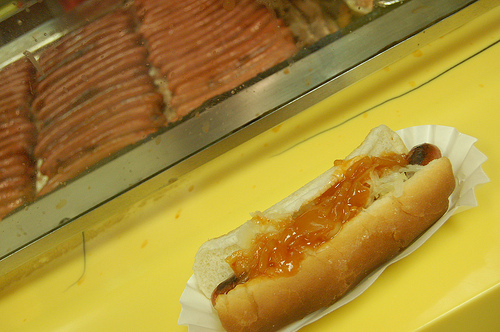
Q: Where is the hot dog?
A: In a wrapper.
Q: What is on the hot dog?
A: Sauce and onions.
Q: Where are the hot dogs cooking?
A: On the rack.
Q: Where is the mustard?
A: On top of the hot dog.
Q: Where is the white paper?
A: Under the hot dog.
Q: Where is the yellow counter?
A: By the hot dog.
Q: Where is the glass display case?
A: Behind the hot dog.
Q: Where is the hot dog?
A: In a paper holder.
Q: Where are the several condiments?
A: On the hot dog.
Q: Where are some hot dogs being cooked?
A: In the glass case.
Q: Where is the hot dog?
A: In a bun.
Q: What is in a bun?
A: The hot dog.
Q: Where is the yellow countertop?
A: Under the hot dog.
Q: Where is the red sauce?
A: On the hot dog.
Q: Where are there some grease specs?
A: On the glass.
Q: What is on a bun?
A: Hot dog.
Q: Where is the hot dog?
A: On a counter.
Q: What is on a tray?
A: Bun.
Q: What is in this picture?
A: White tray with a hot dog on top.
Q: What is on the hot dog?
A: Sauce.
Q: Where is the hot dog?
A: On a yellow counter.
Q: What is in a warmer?
A: Hot dogs.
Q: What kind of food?
A: Grilled hot dog with grilled onions.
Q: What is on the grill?
A: Hot dogs.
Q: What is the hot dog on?
A: Paper.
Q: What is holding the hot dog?
A: A bun.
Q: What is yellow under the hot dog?
A: Counter.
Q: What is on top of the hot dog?
A: Mustard.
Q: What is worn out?
A: Counter top.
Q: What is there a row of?
A: Hot dog buns.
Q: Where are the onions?
A: On hot dog.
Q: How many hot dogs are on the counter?
A: 1.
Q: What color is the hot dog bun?
A: Brown.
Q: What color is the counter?
A: Yellow.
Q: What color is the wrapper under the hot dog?
A: White.